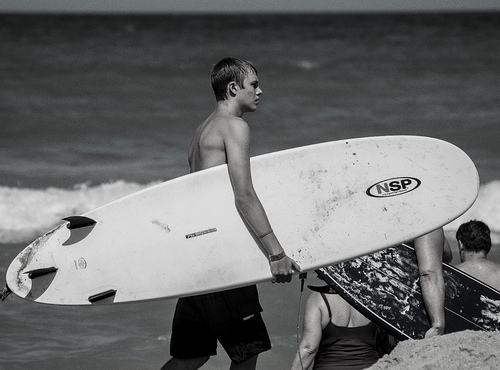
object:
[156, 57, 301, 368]
guy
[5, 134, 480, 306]
surfboard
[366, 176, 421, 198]
logo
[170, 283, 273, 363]
shorts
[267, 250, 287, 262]
bracelets